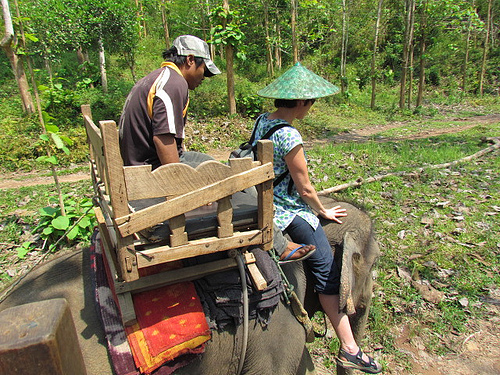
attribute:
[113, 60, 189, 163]
shirt — brown, white, striped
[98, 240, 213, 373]
blanket — red, yellow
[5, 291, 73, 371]
post — wooden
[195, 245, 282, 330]
blanket — grey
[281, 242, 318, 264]
sandal — blue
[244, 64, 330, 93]
hat — green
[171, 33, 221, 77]
baseball cap — man's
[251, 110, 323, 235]
top — white, green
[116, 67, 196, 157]
shirt — man's, brown, yellow, white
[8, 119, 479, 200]
path — dirt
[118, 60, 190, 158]
shirt — man's, grey, yellow, white